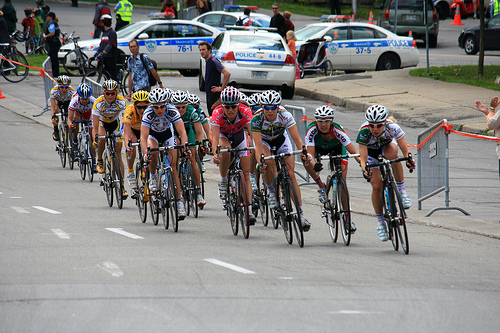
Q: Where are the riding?
A: On the road.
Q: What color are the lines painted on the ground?
A: White.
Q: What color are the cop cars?
A: White with blue writing.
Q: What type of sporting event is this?
A: Bicycle race.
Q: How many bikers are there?
A: More than 10.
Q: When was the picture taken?
A: Daytime.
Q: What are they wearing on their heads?
A: Helmets.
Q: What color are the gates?
A: Gray.